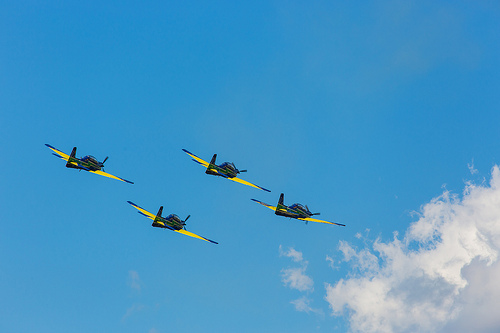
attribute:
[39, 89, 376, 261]
four planes in sky — tight formation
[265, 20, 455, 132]
sky with no clouds — clear, blue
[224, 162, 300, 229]
two plane wings — close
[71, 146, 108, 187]
body of jet — black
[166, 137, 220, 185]
jet has sharp wing — yellow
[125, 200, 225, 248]
wings — yellow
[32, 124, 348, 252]
jets — pictured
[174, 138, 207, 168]
wing — yellow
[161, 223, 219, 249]
wing — sharp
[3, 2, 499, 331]
sky — blue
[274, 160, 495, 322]
clouds — white, cotton-like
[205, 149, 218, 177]
tail — upright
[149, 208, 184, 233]
body — black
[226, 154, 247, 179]
propeller — moving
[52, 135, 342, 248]
wing — yellow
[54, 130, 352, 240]
wing — sharp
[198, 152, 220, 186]
tail — sharp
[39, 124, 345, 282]
planes — flying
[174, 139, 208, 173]
wing — tilted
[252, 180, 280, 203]
tip — dark